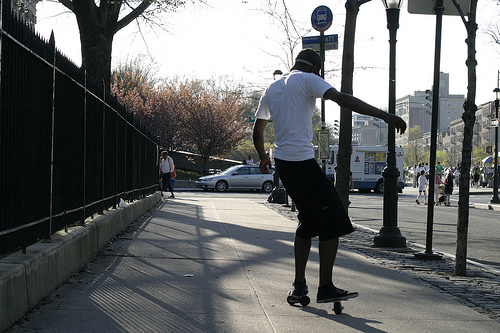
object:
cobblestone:
[379, 262, 383, 265]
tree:
[165, 81, 252, 177]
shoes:
[315, 284, 359, 302]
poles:
[425, 2, 444, 253]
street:
[330, 189, 497, 270]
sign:
[310, 5, 334, 31]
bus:
[317, 8, 328, 21]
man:
[229, 52, 407, 283]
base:
[0, 190, 165, 333]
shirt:
[254, 70, 335, 162]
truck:
[324, 144, 405, 194]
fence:
[2, 21, 160, 257]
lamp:
[381, 0, 404, 10]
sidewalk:
[27, 197, 424, 332]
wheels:
[333, 300, 345, 315]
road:
[348, 187, 499, 268]